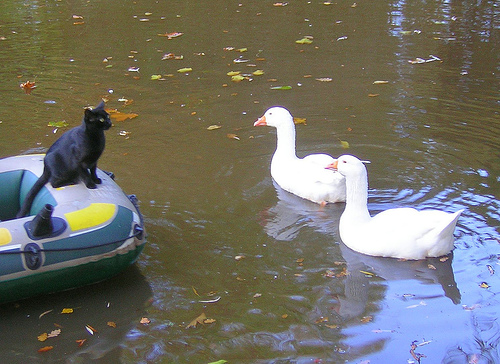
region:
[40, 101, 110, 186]
black cat on inflatable boat.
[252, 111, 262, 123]
orange beak on the duck.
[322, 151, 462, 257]
the duck is swimming.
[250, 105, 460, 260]
two ducks are swimming.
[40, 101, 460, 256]
a cat and two ducks.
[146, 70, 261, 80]
leaves in the water.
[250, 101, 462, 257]
two ducks in a pond.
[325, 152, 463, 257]
the duck is white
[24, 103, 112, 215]
the cat is black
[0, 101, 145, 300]
cat on a boat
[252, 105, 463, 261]
two geese are swimming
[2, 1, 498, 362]
the water is brown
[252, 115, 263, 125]
the beak is orange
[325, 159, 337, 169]
beak of a goose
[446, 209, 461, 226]
tail of a goose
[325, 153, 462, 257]
the goose is white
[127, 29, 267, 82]
leaves floating in water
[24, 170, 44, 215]
tail of a cat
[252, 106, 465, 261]
two white ducks in the water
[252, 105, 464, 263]
two ducks in the water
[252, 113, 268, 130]
orange beaks on a duck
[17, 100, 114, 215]
a black cat sitting on an inflated tube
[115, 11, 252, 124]
leaves on the water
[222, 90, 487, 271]
two white duck in murky water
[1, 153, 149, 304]
a blue, green and white inflated tube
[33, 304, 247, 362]
leaves floating on murky water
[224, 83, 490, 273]
white ducks swimming in murky water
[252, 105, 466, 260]
two ducks watching a black cat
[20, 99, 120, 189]
black cat sitting on a boat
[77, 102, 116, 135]
black cat with green eyes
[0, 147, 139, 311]
green inflatable life raft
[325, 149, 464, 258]
white goose in the water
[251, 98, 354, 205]
white goose in the water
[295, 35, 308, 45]
green leaf in the water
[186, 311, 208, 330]
brown leaf in the water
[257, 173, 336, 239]
reflection of goose in the water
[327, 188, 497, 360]
reflection of the sky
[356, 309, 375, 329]
leaf floating in water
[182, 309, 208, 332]
leaf floating in water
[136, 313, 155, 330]
leaf floating in water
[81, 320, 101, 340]
leaf floating in water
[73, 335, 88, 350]
leaf floating in water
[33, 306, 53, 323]
leaf floating in water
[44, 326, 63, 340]
leaf floating in water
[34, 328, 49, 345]
leaf floating in water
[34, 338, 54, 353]
leaf floating in water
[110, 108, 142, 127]
leaf floating in water